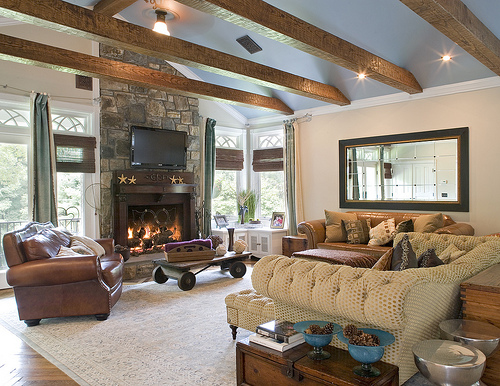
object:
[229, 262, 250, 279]
wheel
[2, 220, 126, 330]
chair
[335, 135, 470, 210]
items/living room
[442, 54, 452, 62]
light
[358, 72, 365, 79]
light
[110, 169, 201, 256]
fireplace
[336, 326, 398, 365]
blue bowl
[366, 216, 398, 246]
pillows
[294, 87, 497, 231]
wall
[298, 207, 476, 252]
chairs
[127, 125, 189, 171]
tv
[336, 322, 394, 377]
items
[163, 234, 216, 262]
items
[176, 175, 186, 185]
items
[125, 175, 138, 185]
items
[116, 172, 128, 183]
items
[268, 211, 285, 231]
framed picture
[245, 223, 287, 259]
table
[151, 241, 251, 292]
item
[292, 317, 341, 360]
item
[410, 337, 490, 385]
item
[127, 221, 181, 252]
fire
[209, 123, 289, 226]
window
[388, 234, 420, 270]
pillows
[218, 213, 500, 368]
chair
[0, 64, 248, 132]
wall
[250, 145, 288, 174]
shade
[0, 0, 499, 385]
living room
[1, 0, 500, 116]
beam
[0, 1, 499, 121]
ceiling